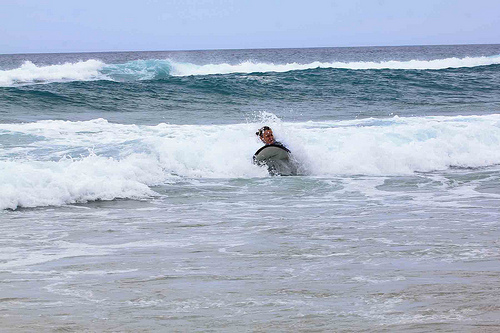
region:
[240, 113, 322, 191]
Man is submerged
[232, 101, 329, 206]
Man is a surfer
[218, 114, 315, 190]
Surfer is on surfboard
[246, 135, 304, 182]
Surfboard is white and black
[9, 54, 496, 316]
The water is blue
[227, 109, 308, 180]
The man is flinching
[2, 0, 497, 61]
The sky is clear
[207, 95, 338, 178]
One man surfing in ocean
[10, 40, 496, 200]
Two white waves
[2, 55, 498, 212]
Two waves crashing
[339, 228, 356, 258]
the water is clear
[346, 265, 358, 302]
the water is clear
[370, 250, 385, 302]
the water is clear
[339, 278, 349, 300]
the water is clear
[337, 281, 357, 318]
the water is clear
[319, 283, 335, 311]
the water is clear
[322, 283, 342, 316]
the water is clear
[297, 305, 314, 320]
the water is clear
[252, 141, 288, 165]
The board being ridden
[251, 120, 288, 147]
The person on the board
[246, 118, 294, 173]
The surfer and his board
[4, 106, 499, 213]
The wave being ridden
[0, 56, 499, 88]
The wave that is just forming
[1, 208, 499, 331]
The calm water in front of the waves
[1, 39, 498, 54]
The horizon line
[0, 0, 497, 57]
The sky above the horizon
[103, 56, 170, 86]
The blue portion of the back wave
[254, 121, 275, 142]
The head of the person on the board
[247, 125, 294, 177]
a man riding a boogie board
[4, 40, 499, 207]
the ocean on a sunny day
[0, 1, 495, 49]
the blue sky above the ocean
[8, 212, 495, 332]
the water on the shore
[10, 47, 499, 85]
the wave in the ocean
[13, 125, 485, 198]
the other wave of the ocean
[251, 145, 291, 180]
the boogie board the man is riding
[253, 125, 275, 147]
the man on the boogie board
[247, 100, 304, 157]
water splashing up above the man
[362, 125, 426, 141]
the lighter part of the ocean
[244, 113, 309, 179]
a body boarder is in the surf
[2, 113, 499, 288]
waves are breaking towards the beach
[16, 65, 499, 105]
a swell is behind the surfer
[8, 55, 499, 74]
the waves are crashing behing the swell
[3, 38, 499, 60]
the ocean has a slight chop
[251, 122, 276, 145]
the person has brown wet hair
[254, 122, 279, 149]
the person's eyes are closed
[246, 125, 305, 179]
the person is half on the board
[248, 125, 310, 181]
the lower half of the person is in the water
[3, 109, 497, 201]
lots of cream is in the water